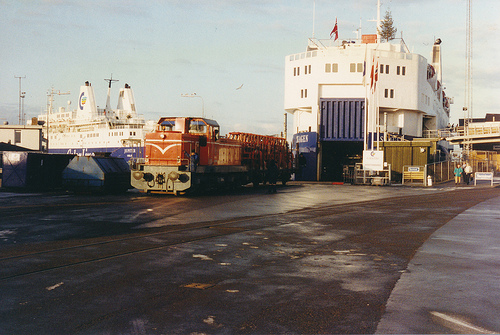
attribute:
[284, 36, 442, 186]
building — white, large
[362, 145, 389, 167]
sign — silver, blue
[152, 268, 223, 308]
line — yellow, painted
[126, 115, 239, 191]
train — converted, white, red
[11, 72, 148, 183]
ship — rusty, white, large, blue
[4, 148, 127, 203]
dumpsters — blue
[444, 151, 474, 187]
people — walking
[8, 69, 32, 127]
pole — wooden, tall, electric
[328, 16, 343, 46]
flag — flying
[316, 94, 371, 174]
door — blue, white, open, garage, metal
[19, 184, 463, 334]
blacktop — parking area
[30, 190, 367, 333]
pavement — dark, wet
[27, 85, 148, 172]
boat — cruise, carnival, white, blue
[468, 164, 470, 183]
man — standing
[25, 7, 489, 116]
sky — cloudy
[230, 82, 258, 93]
birds — flying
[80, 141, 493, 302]
area — cemented